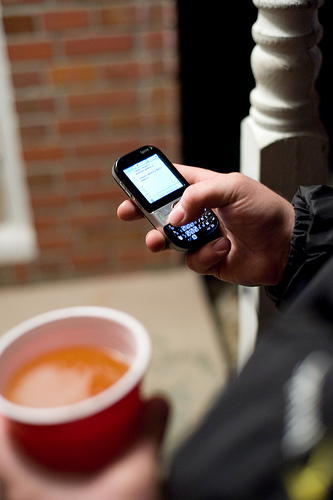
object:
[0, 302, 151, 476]
cup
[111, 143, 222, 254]
cell phone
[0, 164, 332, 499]
man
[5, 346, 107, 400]
orange liquid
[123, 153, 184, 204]
lcd screen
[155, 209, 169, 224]
grey buttons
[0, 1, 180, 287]
brick wall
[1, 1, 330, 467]
background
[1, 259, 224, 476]
grey floor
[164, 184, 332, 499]
black coat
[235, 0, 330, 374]
white rail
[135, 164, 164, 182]
text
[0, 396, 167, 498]
hand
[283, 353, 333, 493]
white and yellow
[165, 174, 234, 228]
thumb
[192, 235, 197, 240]
buttons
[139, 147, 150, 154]
word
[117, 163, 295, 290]
right hand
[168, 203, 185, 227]
thumbnail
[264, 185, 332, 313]
sleeve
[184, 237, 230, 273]
object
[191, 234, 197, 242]
number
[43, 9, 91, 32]
object